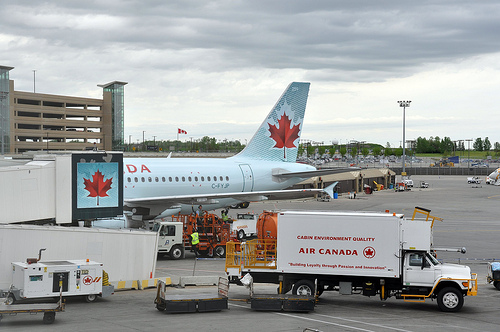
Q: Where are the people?
A: At an airport.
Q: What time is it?
A: Afternoon.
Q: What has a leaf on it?
A: The tail.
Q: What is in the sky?
A: Clouds.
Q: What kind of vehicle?
A: Plane.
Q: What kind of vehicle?
A: Truck.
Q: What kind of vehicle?
A: Plane.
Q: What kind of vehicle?
A: Plane.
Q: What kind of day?
A: Cloduy.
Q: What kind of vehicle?
A: Plane.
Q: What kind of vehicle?
A: Truck.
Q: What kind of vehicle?
A: Plane.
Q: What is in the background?
A: A building.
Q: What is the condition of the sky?
A: Cloudy.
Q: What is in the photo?
A: A Canadian plane.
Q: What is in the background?
A: A building.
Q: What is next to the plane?
A: Trucks.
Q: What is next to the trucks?
A: A plane.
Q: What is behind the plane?
A: A building.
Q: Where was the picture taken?
A: Airport.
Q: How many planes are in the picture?
A: One.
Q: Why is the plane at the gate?
A: Load or Unload passengers.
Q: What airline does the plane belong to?
A: Air Canada.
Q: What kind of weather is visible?
A: Cloudy.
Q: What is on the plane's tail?
A: Maple leaf.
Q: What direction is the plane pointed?
A: Left.